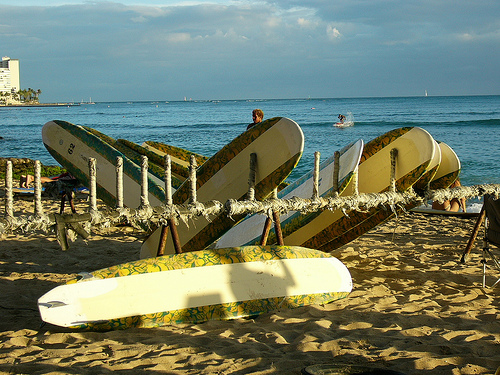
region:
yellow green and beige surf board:
[22, 230, 382, 334]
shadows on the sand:
[292, 309, 488, 373]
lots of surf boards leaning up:
[39, 102, 456, 280]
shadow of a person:
[199, 244, 313, 303]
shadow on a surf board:
[207, 244, 327, 309]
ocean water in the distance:
[97, 92, 219, 147]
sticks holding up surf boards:
[179, 137, 429, 211]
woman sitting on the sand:
[419, 172, 476, 223]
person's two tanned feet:
[14, 166, 65, 201]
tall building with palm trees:
[0, 47, 51, 109]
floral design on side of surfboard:
[93, 255, 170, 287]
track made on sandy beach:
[373, 306, 495, 371]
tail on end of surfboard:
[36, 288, 81, 318]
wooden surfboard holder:
[56, 156, 174, 234]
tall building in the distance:
[0, 48, 32, 103]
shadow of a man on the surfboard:
[226, 249, 321, 346]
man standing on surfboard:
[327, 100, 362, 135]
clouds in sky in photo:
[236, 12, 348, 57]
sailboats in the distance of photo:
[173, 91, 227, 113]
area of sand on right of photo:
[422, 238, 498, 352]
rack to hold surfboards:
[5, 149, 498, 226]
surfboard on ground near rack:
[30, 243, 375, 333]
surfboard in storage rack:
[131, 112, 303, 269]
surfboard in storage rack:
[206, 140, 366, 239]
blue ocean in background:
[15, 87, 498, 214]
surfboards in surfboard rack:
[47, 117, 217, 217]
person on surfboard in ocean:
[331, 111, 356, 129]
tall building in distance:
[1, 54, 23, 106]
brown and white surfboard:
[130, 119, 309, 253]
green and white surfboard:
[209, 145, 369, 245]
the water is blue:
[102, 97, 221, 154]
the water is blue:
[199, 93, 294, 125]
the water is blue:
[116, 109, 198, 134]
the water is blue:
[61, 105, 172, 132]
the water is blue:
[90, 86, 186, 131]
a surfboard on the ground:
[0, 243, 425, 362]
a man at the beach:
[236, 95, 278, 165]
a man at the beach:
[225, 80, 282, 197]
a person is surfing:
[322, 102, 358, 137]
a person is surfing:
[313, 85, 370, 145]